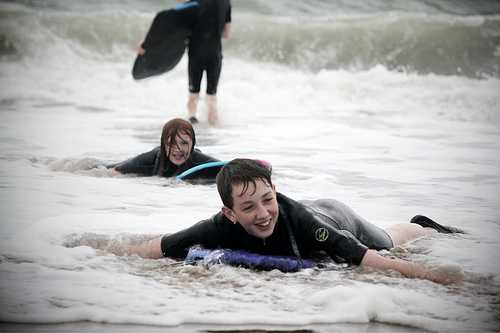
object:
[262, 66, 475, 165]
water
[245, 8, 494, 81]
waves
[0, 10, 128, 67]
wave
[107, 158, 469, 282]
boy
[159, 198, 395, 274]
wet suit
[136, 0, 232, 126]
person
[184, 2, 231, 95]
wet suits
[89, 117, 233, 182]
girl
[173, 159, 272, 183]
surfboard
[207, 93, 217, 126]
bare leg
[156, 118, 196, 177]
wet hair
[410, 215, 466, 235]
wet shoes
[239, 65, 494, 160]
foam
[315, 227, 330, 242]
emblem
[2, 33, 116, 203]
ocean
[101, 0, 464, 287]
kids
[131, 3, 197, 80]
bodyboards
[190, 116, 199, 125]
shoes